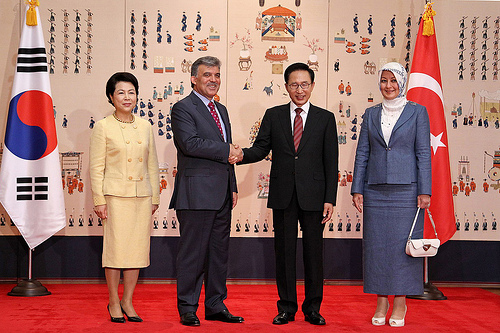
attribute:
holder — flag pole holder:
[24, 277, 34, 283]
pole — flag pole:
[23, 248, 36, 282]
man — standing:
[168, 56, 243, 326]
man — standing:
[228, 52, 339, 325]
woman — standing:
[351, 62, 432, 327]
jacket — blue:
[351, 100, 432, 197]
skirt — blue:
[363, 182, 424, 295]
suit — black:
[236, 101, 338, 314]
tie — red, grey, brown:
[294, 108, 304, 152]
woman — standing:
[90, 72, 161, 323]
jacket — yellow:
[89, 113, 160, 207]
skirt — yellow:
[101, 195, 152, 268]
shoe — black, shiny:
[304, 311, 326, 326]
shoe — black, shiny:
[272, 311, 295, 325]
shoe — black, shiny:
[205, 309, 244, 323]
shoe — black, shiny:
[180, 312, 200, 327]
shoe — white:
[389, 304, 408, 327]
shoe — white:
[371, 300, 389, 325]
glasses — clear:
[286, 82, 314, 91]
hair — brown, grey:
[191, 56, 222, 89]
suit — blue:
[169, 90, 238, 316]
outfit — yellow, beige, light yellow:
[90, 113, 160, 269]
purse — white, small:
[405, 207, 441, 258]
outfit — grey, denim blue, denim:
[351, 101, 432, 296]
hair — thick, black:
[284, 63, 315, 84]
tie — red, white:
[207, 102, 224, 142]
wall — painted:
[0, 0, 500, 284]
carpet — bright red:
[0, 283, 499, 332]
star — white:
[429, 132, 447, 155]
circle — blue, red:
[4, 90, 57, 161]